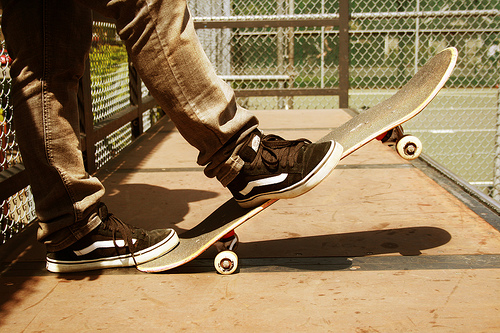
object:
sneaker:
[229, 131, 338, 211]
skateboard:
[131, 44, 461, 276]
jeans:
[0, 0, 261, 251]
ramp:
[4, 102, 500, 333]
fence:
[183, 0, 499, 216]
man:
[0, 0, 346, 271]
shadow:
[156, 221, 451, 271]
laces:
[250, 134, 313, 171]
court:
[226, 87, 498, 211]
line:
[402, 124, 499, 137]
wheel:
[392, 134, 424, 161]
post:
[186, 7, 499, 21]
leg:
[105, 0, 329, 185]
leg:
[1, 0, 100, 254]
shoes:
[38, 205, 175, 282]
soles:
[46, 230, 177, 273]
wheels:
[211, 250, 242, 278]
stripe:
[235, 174, 286, 196]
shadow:
[180, 195, 249, 239]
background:
[0, 0, 499, 333]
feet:
[42, 200, 179, 277]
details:
[224, 231, 233, 244]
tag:
[247, 133, 263, 153]